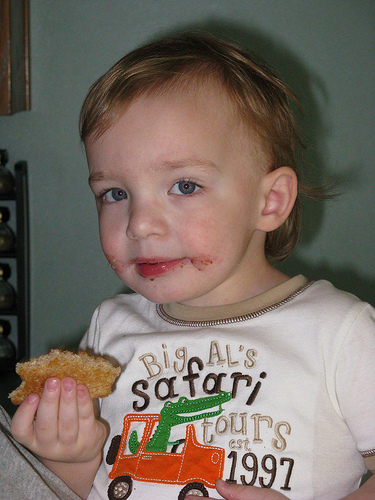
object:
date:
[225, 451, 294, 490]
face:
[82, 96, 252, 304]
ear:
[257, 166, 298, 232]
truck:
[106, 413, 225, 499]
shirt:
[77, 274, 375, 499]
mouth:
[135, 257, 185, 278]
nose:
[126, 197, 170, 240]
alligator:
[128, 390, 232, 454]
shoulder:
[79, 293, 158, 353]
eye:
[167, 181, 202, 195]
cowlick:
[180, 28, 309, 119]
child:
[7, 29, 375, 500]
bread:
[8, 348, 122, 407]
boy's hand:
[9, 377, 106, 464]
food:
[191, 254, 213, 271]